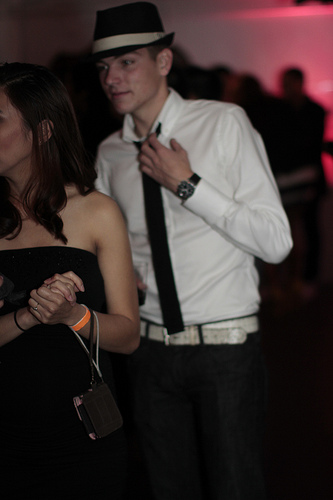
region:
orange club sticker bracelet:
[70, 303, 90, 333]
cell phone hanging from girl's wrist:
[70, 307, 113, 448]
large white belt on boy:
[138, 315, 259, 346]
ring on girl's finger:
[31, 304, 38, 311]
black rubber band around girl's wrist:
[11, 311, 24, 331]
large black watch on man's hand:
[173, 170, 202, 204]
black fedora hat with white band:
[82, 3, 176, 62]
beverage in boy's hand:
[133, 260, 147, 307]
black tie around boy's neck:
[132, 121, 185, 336]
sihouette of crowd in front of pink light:
[181, 0, 330, 191]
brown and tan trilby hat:
[92, 7, 174, 56]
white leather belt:
[143, 321, 260, 342]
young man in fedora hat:
[86, 7, 182, 146]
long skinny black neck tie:
[134, 135, 192, 336]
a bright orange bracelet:
[68, 303, 90, 331]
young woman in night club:
[0, 85, 141, 487]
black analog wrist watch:
[169, 169, 205, 201]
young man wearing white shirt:
[90, 6, 294, 497]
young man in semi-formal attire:
[93, 4, 272, 498]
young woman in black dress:
[0, 94, 107, 366]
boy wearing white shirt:
[89, 0, 293, 482]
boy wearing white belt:
[79, 4, 289, 494]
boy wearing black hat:
[81, 10, 278, 495]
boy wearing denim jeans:
[83, 3, 274, 497]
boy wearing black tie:
[81, 5, 280, 495]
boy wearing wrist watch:
[83, 1, 289, 495]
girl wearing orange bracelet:
[7, 58, 142, 493]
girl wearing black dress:
[0, 58, 143, 493]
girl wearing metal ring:
[1, 58, 137, 494]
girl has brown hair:
[0, 59, 142, 495]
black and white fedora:
[76, 0, 183, 78]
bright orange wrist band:
[57, 290, 93, 341]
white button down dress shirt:
[85, 83, 292, 375]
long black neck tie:
[119, 118, 200, 378]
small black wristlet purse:
[48, 289, 149, 458]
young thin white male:
[87, 0, 298, 399]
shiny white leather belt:
[128, 303, 264, 367]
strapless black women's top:
[0, 200, 140, 408]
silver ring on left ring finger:
[19, 280, 48, 328]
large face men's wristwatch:
[167, 162, 203, 216]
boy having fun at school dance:
[96, 28, 252, 341]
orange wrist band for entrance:
[68, 302, 94, 328]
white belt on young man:
[124, 301, 276, 341]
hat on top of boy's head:
[75, 6, 203, 47]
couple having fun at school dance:
[6, 12, 268, 430]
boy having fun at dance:
[85, 0, 273, 320]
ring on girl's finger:
[31, 300, 47, 309]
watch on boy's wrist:
[164, 167, 214, 197]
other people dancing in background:
[232, 62, 320, 107]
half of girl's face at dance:
[0, 75, 70, 239]